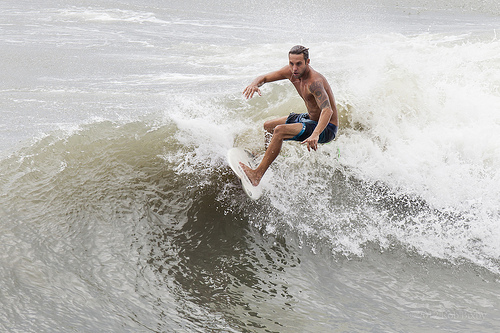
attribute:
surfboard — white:
[216, 128, 260, 195]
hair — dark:
[290, 45, 310, 62]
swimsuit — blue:
[284, 112, 335, 149]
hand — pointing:
[301, 134, 319, 151]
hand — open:
[244, 87, 265, 100]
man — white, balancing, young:
[238, 45, 343, 185]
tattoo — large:
[306, 78, 330, 110]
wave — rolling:
[8, 57, 498, 207]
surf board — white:
[222, 133, 278, 206]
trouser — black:
[290, 118, 335, 142]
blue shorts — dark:
[282, 102, 337, 149]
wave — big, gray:
[9, 42, 497, 316]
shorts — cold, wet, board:
[289, 104, 338, 150]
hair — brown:
[290, 45, 308, 62]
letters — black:
[235, 165, 253, 183]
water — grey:
[84, 146, 376, 323]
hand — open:
[236, 84, 264, 104]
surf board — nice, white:
[229, 144, 261, 199]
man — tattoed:
[201, 42, 338, 199]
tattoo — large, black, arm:
[309, 80, 333, 114]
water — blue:
[26, 21, 496, 314]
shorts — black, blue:
[285, 112, 335, 141]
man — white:
[237, 33, 344, 205]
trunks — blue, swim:
[282, 107, 337, 144]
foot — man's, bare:
[231, 153, 269, 193]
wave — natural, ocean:
[114, 70, 439, 242]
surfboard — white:
[216, 139, 269, 200]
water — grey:
[7, 3, 495, 332]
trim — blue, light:
[294, 114, 304, 138]